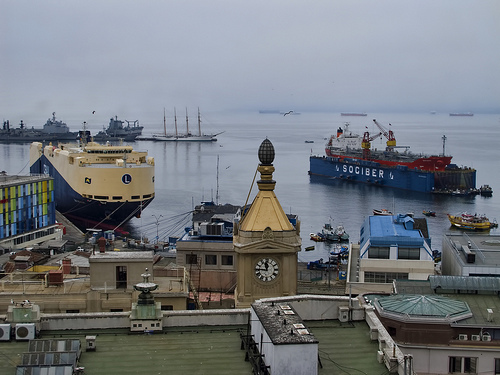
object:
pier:
[0, 108, 499, 296]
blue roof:
[360, 215, 434, 261]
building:
[359, 213, 439, 283]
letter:
[343, 165, 348, 172]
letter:
[349, 166, 354, 173]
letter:
[355, 166, 360, 174]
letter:
[361, 168, 363, 175]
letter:
[365, 168, 370, 176]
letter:
[372, 169, 377, 177]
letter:
[379, 170, 384, 179]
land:
[235, 103, 500, 114]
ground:
[342, 118, 364, 134]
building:
[231, 135, 302, 309]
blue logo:
[121, 173, 131, 184]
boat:
[0, 112, 79, 141]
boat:
[447, 211, 498, 230]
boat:
[91, 107, 143, 141]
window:
[369, 246, 391, 259]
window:
[398, 248, 420, 260]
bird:
[284, 111, 294, 117]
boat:
[152, 107, 226, 142]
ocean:
[0, 113, 499, 262]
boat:
[308, 119, 494, 195]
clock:
[254, 258, 278, 282]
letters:
[336, 165, 384, 179]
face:
[252, 256, 282, 285]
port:
[0, 112, 499, 375]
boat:
[29, 121, 155, 225]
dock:
[0, 232, 169, 298]